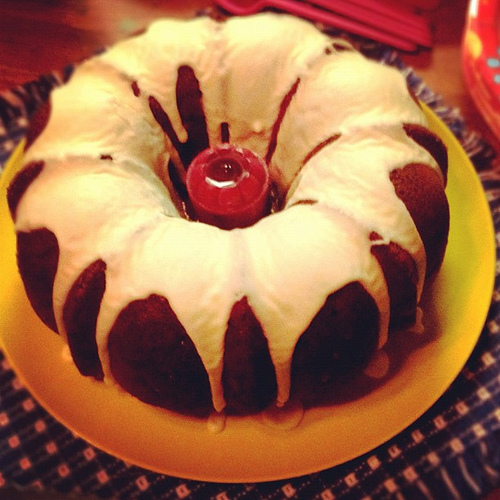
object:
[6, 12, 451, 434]
cake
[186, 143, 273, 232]
candle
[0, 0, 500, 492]
table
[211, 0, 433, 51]
spoons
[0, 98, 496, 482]
plate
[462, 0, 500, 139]
plates